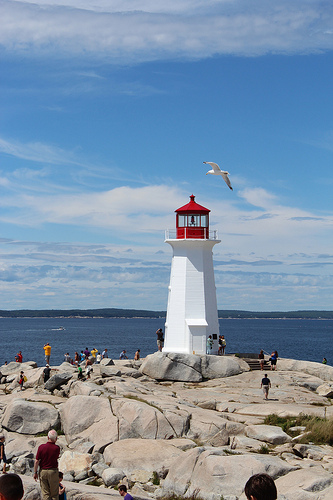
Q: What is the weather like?
A: It is cloudy.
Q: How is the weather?
A: It is cloudy.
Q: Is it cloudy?
A: Yes, it is cloudy.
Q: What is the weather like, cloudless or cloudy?
A: It is cloudy.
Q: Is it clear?
A: No, it is cloudy.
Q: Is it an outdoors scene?
A: Yes, it is outdoors.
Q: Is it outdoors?
A: Yes, it is outdoors.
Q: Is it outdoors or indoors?
A: It is outdoors.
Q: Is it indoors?
A: No, it is outdoors.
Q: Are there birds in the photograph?
A: Yes, there is a bird.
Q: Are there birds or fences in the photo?
A: Yes, there is a bird.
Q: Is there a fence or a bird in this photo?
A: Yes, there is a bird.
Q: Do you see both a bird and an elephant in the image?
A: No, there is a bird but no elephants.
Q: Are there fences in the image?
A: No, there are no fences.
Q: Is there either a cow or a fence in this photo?
A: No, there are no fences or cows.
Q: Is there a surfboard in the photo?
A: No, there are no surfboards.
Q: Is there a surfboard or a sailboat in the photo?
A: No, there are no surfboards or sailboats.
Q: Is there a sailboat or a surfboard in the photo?
A: No, there are no surfboards or sailboats.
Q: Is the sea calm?
A: Yes, the sea is calm.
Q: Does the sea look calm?
A: Yes, the sea is calm.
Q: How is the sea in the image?
A: The sea is calm.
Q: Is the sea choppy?
A: No, the sea is calm.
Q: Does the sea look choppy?
A: No, the sea is calm.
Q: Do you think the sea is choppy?
A: No, the sea is calm.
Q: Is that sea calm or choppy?
A: The sea is calm.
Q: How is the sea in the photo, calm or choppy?
A: The sea is calm.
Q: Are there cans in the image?
A: No, there are no cans.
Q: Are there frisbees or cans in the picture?
A: No, there are no cans or frisbees.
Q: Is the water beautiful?
A: Yes, the water is beautiful.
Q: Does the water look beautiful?
A: Yes, the water is beautiful.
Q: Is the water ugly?
A: No, the water is beautiful.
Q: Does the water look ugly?
A: No, the water is beautiful.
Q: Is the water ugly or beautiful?
A: The water is beautiful.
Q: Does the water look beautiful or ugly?
A: The water is beautiful.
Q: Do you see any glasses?
A: No, there are no glasses.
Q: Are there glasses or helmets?
A: No, there are no glasses or helmets.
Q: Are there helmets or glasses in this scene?
A: No, there are no glasses or helmets.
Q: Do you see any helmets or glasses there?
A: No, there are no glasses or helmets.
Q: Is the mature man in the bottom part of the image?
A: Yes, the man is in the bottom of the image.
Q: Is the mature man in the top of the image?
A: No, the man is in the bottom of the image.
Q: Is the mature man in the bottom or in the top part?
A: The man is in the bottom of the image.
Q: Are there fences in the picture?
A: No, there are no fences.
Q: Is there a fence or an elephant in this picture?
A: No, there are no fences or elephants.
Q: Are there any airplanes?
A: No, there are no airplanes.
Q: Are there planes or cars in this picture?
A: No, there are no planes or cars.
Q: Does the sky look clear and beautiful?
A: No, the sky is beautiful but cloudy.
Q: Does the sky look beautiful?
A: Yes, the sky is beautiful.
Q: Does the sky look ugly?
A: No, the sky is beautiful.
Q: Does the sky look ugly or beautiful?
A: The sky is beautiful.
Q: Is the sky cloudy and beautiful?
A: Yes, the sky is cloudy and beautiful.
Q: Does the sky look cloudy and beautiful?
A: Yes, the sky is cloudy and beautiful.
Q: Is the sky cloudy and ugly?
A: No, the sky is cloudy but beautiful.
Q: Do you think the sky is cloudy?
A: Yes, the sky is cloudy.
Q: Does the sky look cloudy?
A: Yes, the sky is cloudy.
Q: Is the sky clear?
A: No, the sky is cloudy.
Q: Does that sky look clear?
A: No, the sky is cloudy.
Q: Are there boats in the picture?
A: No, there are no boats.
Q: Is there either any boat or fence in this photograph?
A: No, there are no boats or fences.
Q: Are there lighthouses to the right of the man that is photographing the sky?
A: Yes, there is a lighthouse to the right of the man.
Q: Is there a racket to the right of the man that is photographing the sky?
A: No, there is a lighthouse to the right of the man.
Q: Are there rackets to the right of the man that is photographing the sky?
A: No, there is a lighthouse to the right of the man.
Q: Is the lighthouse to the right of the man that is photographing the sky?
A: Yes, the lighthouse is to the right of the man.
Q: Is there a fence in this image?
A: No, there are no fences.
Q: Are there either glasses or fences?
A: No, there are no fences or glasses.